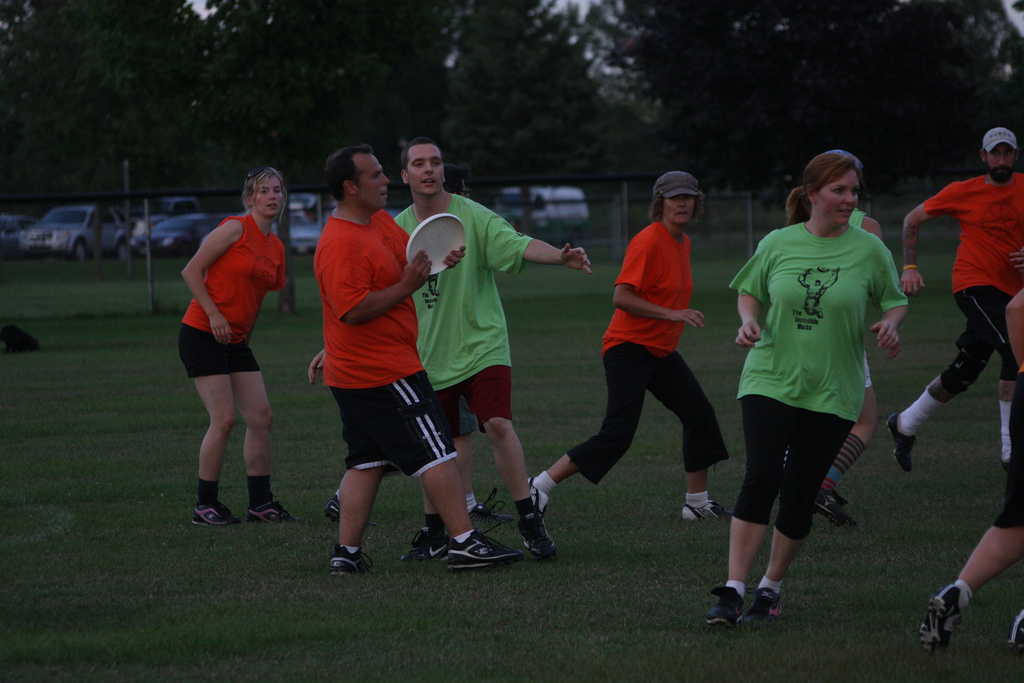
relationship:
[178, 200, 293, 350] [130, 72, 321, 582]
shirt worn by woman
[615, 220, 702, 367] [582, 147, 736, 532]
shirt worn by woman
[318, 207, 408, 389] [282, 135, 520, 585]
shirt worn by man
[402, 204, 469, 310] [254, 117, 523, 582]
frisbee held by man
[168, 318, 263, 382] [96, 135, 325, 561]
shorts worn by woman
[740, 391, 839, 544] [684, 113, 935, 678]
capris worn by woman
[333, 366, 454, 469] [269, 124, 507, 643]
shorts worn by man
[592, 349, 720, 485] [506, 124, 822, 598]
pants worn by woman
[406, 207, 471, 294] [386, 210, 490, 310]
man holding frisbee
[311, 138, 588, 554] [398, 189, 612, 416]
man in shirt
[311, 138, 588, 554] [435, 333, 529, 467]
man in shorts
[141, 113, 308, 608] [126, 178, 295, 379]
woman with one arm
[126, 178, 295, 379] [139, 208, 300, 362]
arm in a shirt